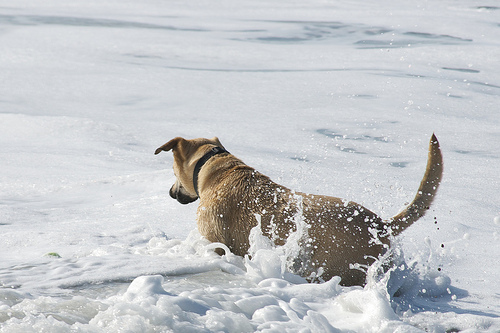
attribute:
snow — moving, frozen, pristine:
[202, 11, 490, 318]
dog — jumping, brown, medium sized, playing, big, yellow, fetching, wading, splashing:
[154, 132, 444, 290]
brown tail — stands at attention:
[382, 131, 445, 236]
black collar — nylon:
[193, 147, 230, 197]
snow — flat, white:
[0, 0, 500, 332]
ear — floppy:
[154, 137, 182, 156]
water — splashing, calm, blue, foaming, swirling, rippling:
[0, 253, 430, 332]